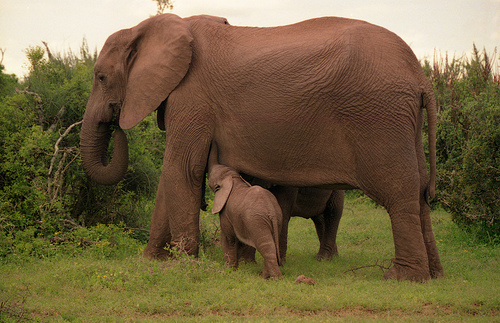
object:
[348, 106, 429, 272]
leg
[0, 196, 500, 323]
field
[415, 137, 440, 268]
leg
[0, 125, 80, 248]
trees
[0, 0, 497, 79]
sky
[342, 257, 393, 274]
branch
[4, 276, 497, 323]
ground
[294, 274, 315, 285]
brown rock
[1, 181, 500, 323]
grass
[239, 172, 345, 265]
elephant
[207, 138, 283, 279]
baby elephant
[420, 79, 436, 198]
tail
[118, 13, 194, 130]
ear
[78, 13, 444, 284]
mother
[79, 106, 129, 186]
trunk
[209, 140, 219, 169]
trunk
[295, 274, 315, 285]
poop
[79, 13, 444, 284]
elephant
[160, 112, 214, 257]
front leg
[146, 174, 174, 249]
front leg